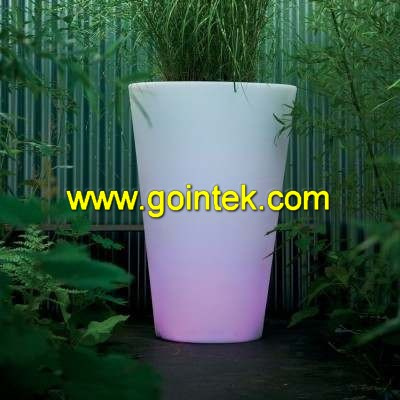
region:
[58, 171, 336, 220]
a website address on a cup.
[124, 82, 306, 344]
a white cup on the ground.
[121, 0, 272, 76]
a green plant above a cup.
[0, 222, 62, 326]
a leafy green tree.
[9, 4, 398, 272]
a white fence.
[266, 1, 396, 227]
a leafy green tree.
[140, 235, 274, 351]
a purple colored cup bottom.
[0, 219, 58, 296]
a tree with lots of leaves.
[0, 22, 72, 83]
plants on a fence.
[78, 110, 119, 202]
a tall board.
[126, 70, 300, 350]
A large white pot.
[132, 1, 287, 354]
The plant is green.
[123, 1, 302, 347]
The plant is living.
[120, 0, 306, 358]
The plant is leafy.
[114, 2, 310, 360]
The plant is flourishing.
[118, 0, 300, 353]
The plant is verduous.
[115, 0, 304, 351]
The plant is growing.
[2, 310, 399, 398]
Area beneath pot is green.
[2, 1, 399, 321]
The background wall is green.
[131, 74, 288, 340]
Purple cup in forrest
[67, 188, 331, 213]
Yellow lettering on screen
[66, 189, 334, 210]
Yellow website address on screen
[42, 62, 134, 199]
Metal fenced in area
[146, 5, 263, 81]
Green bushes area behind cup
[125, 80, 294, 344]
Lit cup in park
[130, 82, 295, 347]
Artwork in garden area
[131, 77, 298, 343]
Multiple colored cup in park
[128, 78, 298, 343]
Violet cup in wooded area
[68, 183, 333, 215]
Company website address on cup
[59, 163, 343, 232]
Yellow letters of website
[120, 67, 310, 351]
A tall white planter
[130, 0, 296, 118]
Green plant inside planter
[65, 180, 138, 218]
Three W's in a row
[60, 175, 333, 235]
Yellow letters in front of planter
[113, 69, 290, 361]
A white round planter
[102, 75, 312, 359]
White planter with pink at the bottom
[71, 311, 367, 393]
Black flooring under planter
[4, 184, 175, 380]
Green foilage around planter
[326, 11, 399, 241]
Long stem of plant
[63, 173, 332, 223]
yellow site of web page address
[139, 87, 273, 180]
large white planter with plant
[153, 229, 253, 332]
large white planter with plant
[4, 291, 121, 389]
large leaves of green plant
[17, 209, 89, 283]
large leaves of green plant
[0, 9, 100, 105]
large leaves of green plant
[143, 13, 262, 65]
large leaves of green plant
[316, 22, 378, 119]
large leaves of green plant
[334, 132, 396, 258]
large leaves of green plant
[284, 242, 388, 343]
large leaves of green plant